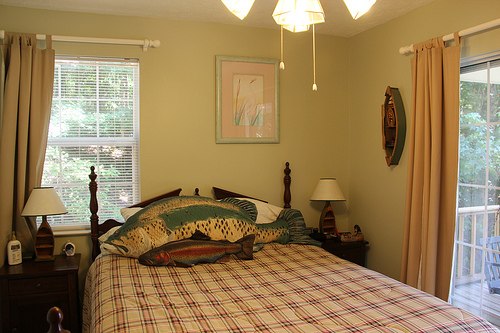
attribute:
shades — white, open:
[31, 55, 143, 225]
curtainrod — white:
[396, 17, 499, 57]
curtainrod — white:
[0, 27, 160, 49]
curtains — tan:
[0, 27, 56, 269]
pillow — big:
[108, 199, 308, 255]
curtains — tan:
[402, 36, 461, 303]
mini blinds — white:
[41, 59, 133, 223]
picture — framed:
[214, 55, 280, 144]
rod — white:
[0, 30, 160, 51]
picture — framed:
[207, 46, 290, 150]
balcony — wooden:
[421, 160, 489, 321]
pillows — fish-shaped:
[102, 196, 316, 268]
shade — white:
[303, 175, 345, 202]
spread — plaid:
[247, 265, 363, 327]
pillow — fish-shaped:
[229, 194, 282, 243]